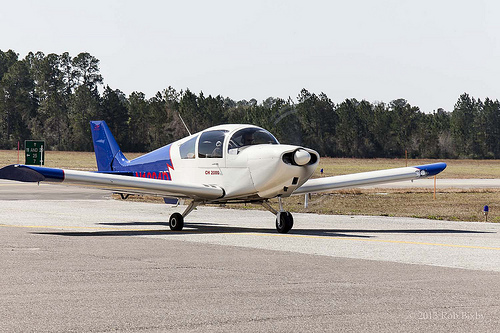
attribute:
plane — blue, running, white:
[102, 122, 321, 213]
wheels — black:
[164, 207, 309, 240]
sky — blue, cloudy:
[188, 3, 306, 53]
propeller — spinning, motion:
[290, 149, 316, 165]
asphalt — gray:
[39, 226, 112, 296]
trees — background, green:
[38, 61, 140, 135]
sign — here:
[17, 132, 59, 167]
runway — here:
[317, 216, 394, 301]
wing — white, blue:
[1, 156, 176, 186]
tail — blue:
[86, 108, 128, 159]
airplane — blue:
[162, 106, 228, 242]